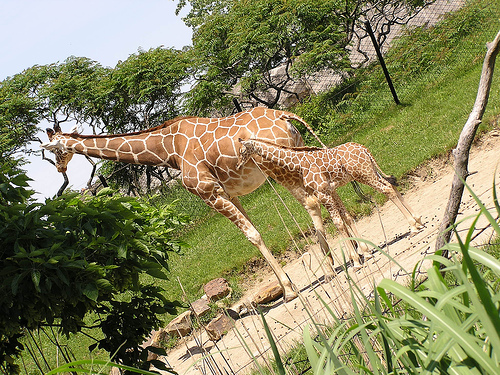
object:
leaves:
[129, 239, 151, 255]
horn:
[45, 127, 53, 138]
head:
[38, 124, 73, 172]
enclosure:
[0, 0, 497, 369]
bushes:
[0, 167, 497, 375]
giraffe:
[234, 136, 422, 273]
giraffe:
[39, 107, 370, 303]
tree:
[2, 127, 200, 370]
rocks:
[201, 276, 232, 302]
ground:
[0, 62, 500, 375]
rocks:
[245, 278, 283, 302]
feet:
[323, 273, 336, 284]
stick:
[435, 27, 500, 263]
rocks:
[224, 298, 255, 319]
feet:
[406, 226, 421, 238]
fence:
[137, 2, 500, 253]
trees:
[161, 0, 349, 129]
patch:
[121, 135, 500, 375]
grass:
[0, 0, 500, 375]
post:
[362, 22, 400, 105]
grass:
[304, 258, 500, 375]